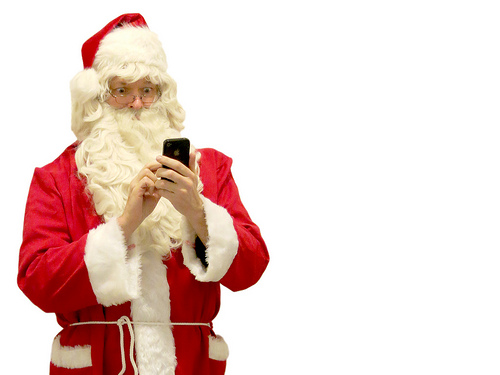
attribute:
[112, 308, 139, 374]
string — white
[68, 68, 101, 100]
ball — white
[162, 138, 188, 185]
cellphone — black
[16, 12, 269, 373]
costume — white 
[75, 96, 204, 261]
beard — white 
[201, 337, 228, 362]
trim — fur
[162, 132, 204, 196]
cell phone — cell , black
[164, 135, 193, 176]
phone — cell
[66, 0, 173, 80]
hat — red and white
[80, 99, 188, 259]
beard — long, white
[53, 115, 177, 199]
beard — long, white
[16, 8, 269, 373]
santa costume — Red 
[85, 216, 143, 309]
cuff — white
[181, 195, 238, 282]
cuff — white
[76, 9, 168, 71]
hat — white, felt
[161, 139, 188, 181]
cell phone — black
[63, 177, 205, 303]
coat — red and white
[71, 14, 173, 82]
hat — red, Santa Claus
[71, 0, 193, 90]
cap — white , red 